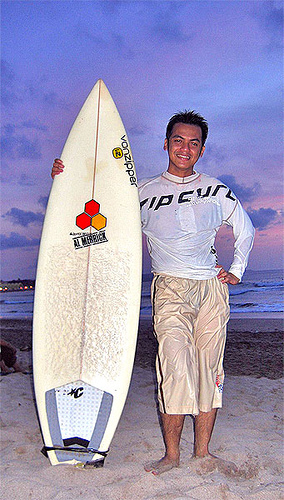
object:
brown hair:
[166, 107, 209, 152]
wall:
[221, 81, 244, 113]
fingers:
[51, 159, 65, 180]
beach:
[0, 318, 284, 500]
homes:
[0, 282, 33, 292]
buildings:
[0, 282, 32, 290]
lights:
[0, 285, 33, 292]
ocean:
[0, 270, 284, 315]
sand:
[0, 366, 284, 500]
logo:
[112, 135, 138, 188]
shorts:
[150, 271, 231, 417]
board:
[32, 79, 143, 469]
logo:
[140, 184, 235, 212]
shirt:
[137, 169, 255, 283]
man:
[51, 107, 255, 475]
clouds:
[0, 0, 284, 271]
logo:
[69, 199, 108, 251]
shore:
[0, 311, 284, 380]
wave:
[0, 271, 284, 314]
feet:
[144, 451, 238, 476]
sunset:
[247, 210, 281, 274]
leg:
[193, 408, 219, 453]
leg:
[160, 411, 185, 458]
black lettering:
[140, 185, 236, 212]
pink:
[247, 201, 283, 269]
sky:
[0, 0, 283, 283]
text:
[69, 229, 108, 250]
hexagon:
[84, 199, 100, 217]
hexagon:
[91, 213, 107, 231]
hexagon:
[76, 212, 91, 230]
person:
[0, 338, 29, 374]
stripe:
[151, 275, 166, 414]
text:
[140, 185, 236, 212]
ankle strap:
[40, 446, 108, 469]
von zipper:
[120, 134, 137, 187]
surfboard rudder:
[40, 379, 113, 468]